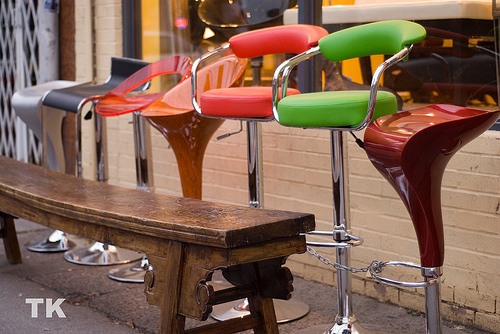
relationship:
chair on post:
[271, 15, 423, 128] [305, 131, 357, 333]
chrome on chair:
[44, 105, 110, 186] [43, 56, 152, 117]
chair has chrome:
[191, 16, 327, 123] [215, 122, 270, 198]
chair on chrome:
[191, 16, 327, 123] [215, 122, 270, 198]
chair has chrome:
[43, 56, 152, 117] [44, 105, 110, 186]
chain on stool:
[309, 251, 381, 279] [360, 105, 497, 333]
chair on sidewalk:
[271, 15, 423, 128] [1, 225, 499, 334]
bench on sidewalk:
[1, 163, 317, 333] [1, 225, 499, 334]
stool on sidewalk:
[360, 105, 497, 333] [1, 225, 499, 334]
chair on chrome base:
[191, 16, 327, 123] [208, 277, 313, 328]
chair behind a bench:
[271, 18, 426, 131] [1, 163, 317, 333]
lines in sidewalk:
[25, 267, 150, 333] [1, 225, 499, 334]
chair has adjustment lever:
[191, 16, 327, 123] [210, 121, 247, 144]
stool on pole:
[360, 105, 497, 333] [424, 271, 445, 333]